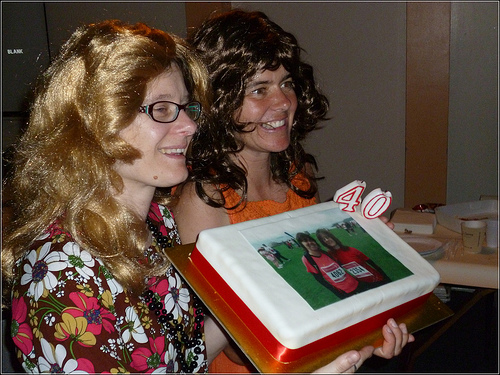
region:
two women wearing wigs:
[21, 15, 337, 199]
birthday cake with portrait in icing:
[160, 175, 461, 363]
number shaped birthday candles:
[322, 164, 393, 230]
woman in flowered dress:
[7, 17, 211, 374]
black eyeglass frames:
[110, 95, 205, 132]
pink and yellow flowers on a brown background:
[40, 277, 123, 352]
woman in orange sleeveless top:
[198, 21, 334, 233]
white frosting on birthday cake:
[199, 226, 251, 288]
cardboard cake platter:
[156, 231, 246, 338]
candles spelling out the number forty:
[326, 171, 396, 230]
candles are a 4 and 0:
[335, 165, 408, 228]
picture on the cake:
[231, 215, 423, 298]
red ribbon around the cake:
[191, 247, 306, 363]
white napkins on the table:
[384, 198, 451, 240]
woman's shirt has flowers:
[37, 211, 182, 347]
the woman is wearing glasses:
[115, 69, 216, 154]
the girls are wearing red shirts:
[290, 237, 406, 295]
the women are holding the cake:
[183, 260, 445, 373]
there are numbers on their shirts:
[326, 257, 375, 290]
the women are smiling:
[147, 127, 324, 166]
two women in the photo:
[43, 41, 339, 223]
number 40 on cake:
[334, 175, 399, 224]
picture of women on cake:
[280, 221, 369, 277]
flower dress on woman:
[41, 245, 172, 365]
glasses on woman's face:
[128, 66, 207, 143]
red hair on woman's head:
[0, 49, 192, 239]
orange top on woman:
[220, 170, 323, 220]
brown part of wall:
[386, 5, 460, 182]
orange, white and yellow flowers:
[23, 257, 129, 353]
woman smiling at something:
[95, 67, 209, 207]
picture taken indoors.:
[34, 29, 455, 357]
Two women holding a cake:
[58, 56, 355, 209]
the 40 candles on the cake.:
[308, 137, 415, 267]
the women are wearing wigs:
[71, 51, 357, 138]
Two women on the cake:
[280, 213, 428, 365]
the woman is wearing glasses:
[101, 81, 211, 122]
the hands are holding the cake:
[311, 321, 401, 369]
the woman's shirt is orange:
[222, 182, 326, 206]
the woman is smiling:
[249, 112, 300, 140]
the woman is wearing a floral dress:
[27, 256, 214, 369]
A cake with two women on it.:
[160, 154, 453, 374]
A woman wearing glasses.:
[50, 42, 210, 246]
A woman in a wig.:
[180, 1, 357, 189]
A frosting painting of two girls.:
[283, 228, 371, 324]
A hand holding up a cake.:
[354, 281, 447, 358]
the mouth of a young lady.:
[255, 111, 307, 141]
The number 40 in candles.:
[306, 163, 435, 253]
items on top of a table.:
[407, 211, 478, 261]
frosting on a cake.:
[213, 261, 240, 311]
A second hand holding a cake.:
[313, 340, 379, 374]